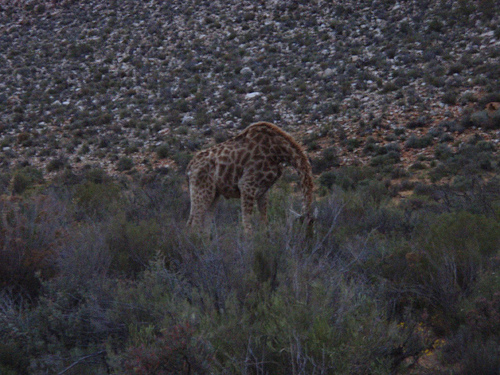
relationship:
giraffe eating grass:
[181, 119, 319, 242] [1, 154, 499, 375]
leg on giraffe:
[239, 193, 256, 235] [181, 119, 319, 242]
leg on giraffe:
[256, 193, 271, 232] [181, 119, 319, 242]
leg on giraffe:
[185, 181, 217, 234] [181, 119, 319, 242]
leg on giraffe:
[200, 191, 221, 242] [181, 119, 319, 242]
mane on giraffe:
[245, 120, 314, 208] [181, 119, 319, 242]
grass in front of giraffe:
[1, 154, 499, 375] [181, 119, 319, 242]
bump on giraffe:
[192, 158, 212, 187] [181, 119, 319, 242]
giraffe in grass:
[181, 119, 319, 242] [1, 154, 499, 375]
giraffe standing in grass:
[181, 119, 319, 242] [1, 154, 499, 375]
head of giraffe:
[288, 208, 320, 257] [181, 119, 319, 242]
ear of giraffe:
[288, 208, 301, 223] [181, 119, 319, 242]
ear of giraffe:
[305, 205, 317, 223] [181, 119, 319, 242]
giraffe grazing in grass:
[181, 119, 319, 242] [1, 154, 499, 375]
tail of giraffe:
[184, 169, 192, 231] [181, 119, 319, 242]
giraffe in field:
[181, 119, 319, 242] [1, 3, 495, 371]